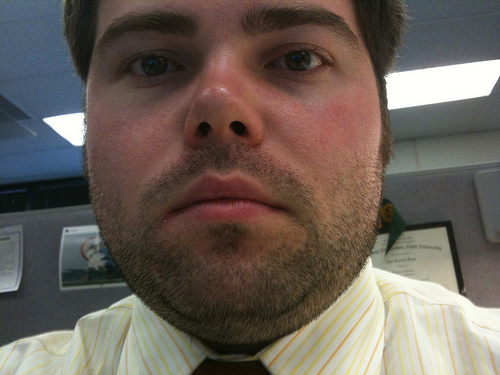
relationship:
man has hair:
[59, 1, 408, 342] [61, 1, 407, 88]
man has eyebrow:
[59, 1, 408, 342] [93, 10, 203, 52]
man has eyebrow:
[59, 1, 408, 342] [242, 9, 364, 55]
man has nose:
[59, 1, 408, 342] [184, 47, 264, 140]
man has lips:
[59, 1, 408, 342] [177, 170, 281, 220]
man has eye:
[59, 1, 408, 342] [120, 49, 187, 80]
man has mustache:
[59, 1, 408, 342] [143, 143, 320, 223]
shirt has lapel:
[0, 258, 499, 374] [115, 277, 388, 374]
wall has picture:
[2, 153, 497, 346] [58, 225, 127, 290]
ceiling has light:
[1, 2, 499, 190] [42, 106, 96, 150]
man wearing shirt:
[59, 1, 408, 342] [0, 258, 499, 374]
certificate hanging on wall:
[361, 220, 462, 296] [2, 153, 497, 346]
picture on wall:
[58, 225, 127, 290] [2, 153, 497, 346]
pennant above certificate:
[377, 196, 404, 254] [361, 220, 462, 296]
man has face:
[59, 1, 408, 342] [92, 9, 369, 281]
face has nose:
[92, 9, 369, 281] [184, 47, 264, 140]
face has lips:
[92, 9, 369, 281] [177, 170, 281, 220]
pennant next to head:
[377, 196, 404, 254] [70, 2, 412, 345]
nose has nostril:
[184, 47, 264, 140] [195, 118, 215, 141]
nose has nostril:
[184, 47, 264, 140] [229, 116, 251, 143]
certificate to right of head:
[361, 220, 462, 296] [70, 2, 412, 345]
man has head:
[59, 1, 408, 342] [70, 2, 412, 345]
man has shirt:
[59, 1, 408, 342] [0, 258, 499, 374]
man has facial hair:
[59, 1, 408, 342] [85, 132, 392, 347]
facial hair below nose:
[85, 132, 392, 347] [184, 47, 264, 140]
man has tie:
[59, 1, 408, 342] [190, 353, 267, 374]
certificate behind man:
[361, 220, 462, 296] [59, 1, 408, 342]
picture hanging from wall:
[58, 225, 127, 290] [2, 153, 497, 346]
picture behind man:
[58, 225, 127, 290] [59, 1, 408, 342]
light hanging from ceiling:
[42, 106, 96, 150] [1, 2, 499, 190]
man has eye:
[59, 1, 408, 342] [265, 45, 324, 75]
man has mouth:
[59, 1, 408, 342] [167, 169, 292, 232]